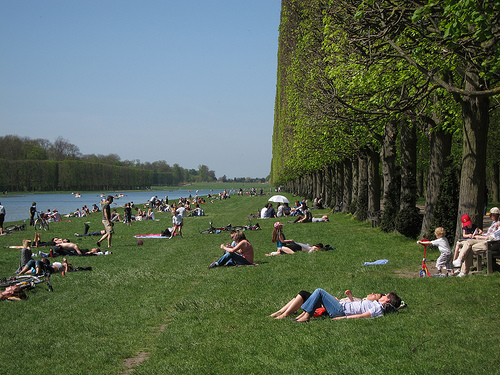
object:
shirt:
[342, 300, 381, 315]